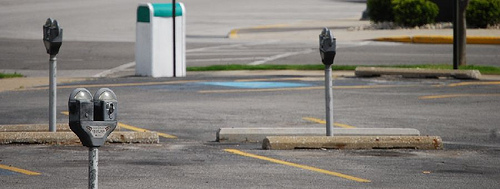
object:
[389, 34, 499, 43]
paint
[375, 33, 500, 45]
curb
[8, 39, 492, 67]
street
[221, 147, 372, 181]
marker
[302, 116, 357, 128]
marker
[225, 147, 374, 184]
stripe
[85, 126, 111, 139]
sign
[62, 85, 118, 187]
parking meter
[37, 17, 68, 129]
parking meter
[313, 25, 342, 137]
parking meter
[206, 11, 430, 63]
side walk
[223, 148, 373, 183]
line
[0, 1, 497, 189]
pavement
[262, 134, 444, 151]
cement slab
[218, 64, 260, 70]
grass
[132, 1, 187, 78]
can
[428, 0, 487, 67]
tree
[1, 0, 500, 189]
lot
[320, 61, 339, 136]
post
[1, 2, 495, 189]
road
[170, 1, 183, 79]
pole